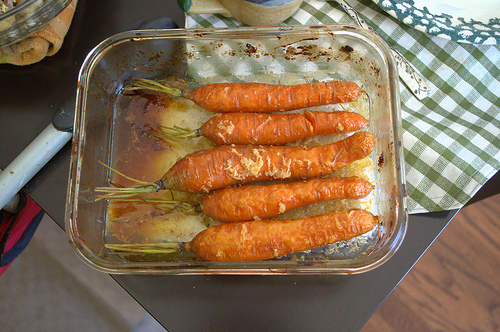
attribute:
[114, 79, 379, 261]
carrots — orange, baked, whole, prepped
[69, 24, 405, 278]
pan — glass, rectangular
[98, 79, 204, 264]
roots — lateral, green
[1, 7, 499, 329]
floor — wooden, wood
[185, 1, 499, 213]
cloth — checkered, green, white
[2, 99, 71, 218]
handle — metal, silver, here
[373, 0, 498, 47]
plate — white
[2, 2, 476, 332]
table — wooden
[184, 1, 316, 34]
mug — ceramic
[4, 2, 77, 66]
towel — folded, rolled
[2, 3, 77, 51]
bowl — clear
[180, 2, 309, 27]
cup — pottery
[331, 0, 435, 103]
utensil — silver